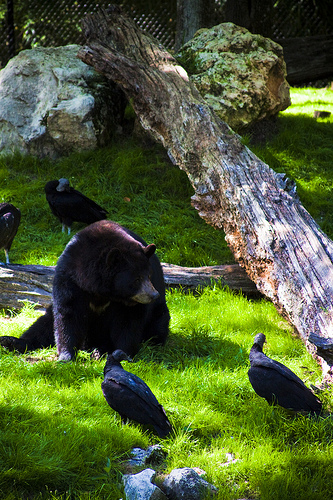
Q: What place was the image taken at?
A: It was taken at the lawn.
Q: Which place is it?
A: It is a lawn.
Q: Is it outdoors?
A: Yes, it is outdoors.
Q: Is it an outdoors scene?
A: Yes, it is outdoors.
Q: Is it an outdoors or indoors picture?
A: It is outdoors.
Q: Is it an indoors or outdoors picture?
A: It is outdoors.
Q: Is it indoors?
A: No, it is outdoors.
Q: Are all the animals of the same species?
A: No, there are both birds and bears.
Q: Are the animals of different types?
A: Yes, they are birds and bears.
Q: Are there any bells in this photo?
A: No, there are no bells.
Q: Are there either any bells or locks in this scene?
A: No, there are no bells or locks.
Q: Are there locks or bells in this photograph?
A: No, there are no bells or locks.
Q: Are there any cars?
A: No, there are no cars.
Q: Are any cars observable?
A: No, there are no cars.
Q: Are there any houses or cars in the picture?
A: No, there are no cars or houses.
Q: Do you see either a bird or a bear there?
A: Yes, there is a bird.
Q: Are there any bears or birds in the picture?
A: Yes, there is a bird.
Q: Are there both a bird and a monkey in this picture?
A: No, there is a bird but no monkeys.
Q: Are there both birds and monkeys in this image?
A: No, there is a bird but no monkeys.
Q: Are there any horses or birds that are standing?
A: Yes, the bird is standing.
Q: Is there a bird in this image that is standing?
A: Yes, there is a bird that is standing.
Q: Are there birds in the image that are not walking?
A: Yes, there is a bird that is standing.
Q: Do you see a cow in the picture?
A: No, there are no cows.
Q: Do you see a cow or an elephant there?
A: No, there are no cows or elephants.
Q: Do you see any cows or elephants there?
A: No, there are no cows or elephants.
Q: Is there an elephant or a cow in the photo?
A: No, there are no cows or elephants.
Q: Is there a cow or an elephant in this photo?
A: No, there are no cows or elephants.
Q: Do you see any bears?
A: Yes, there is a bear.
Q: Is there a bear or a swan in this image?
A: Yes, there is a bear.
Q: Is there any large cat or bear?
A: Yes, there is a large bear.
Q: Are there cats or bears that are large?
A: Yes, the bear is large.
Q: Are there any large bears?
A: Yes, there is a large bear.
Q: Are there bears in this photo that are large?
A: Yes, there is a bear that is large.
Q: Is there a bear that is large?
A: Yes, there is a bear that is large.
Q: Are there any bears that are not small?
A: Yes, there is a large bear.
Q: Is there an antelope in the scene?
A: No, there are no antelopes.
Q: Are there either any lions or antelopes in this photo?
A: No, there are no antelopes or lions.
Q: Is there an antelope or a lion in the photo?
A: No, there are no antelopes or lions.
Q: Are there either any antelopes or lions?
A: No, there are no antelopes or lions.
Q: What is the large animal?
A: The animal is a bear.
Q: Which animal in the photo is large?
A: The animal is a bear.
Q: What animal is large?
A: The animal is a bear.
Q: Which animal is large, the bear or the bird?
A: The bear is large.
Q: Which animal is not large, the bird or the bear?
A: The bird is not large.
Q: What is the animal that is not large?
A: The animal is a bird.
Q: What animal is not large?
A: The animal is a bird.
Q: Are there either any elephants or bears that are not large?
A: No, there is a bear but it is large.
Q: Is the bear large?
A: Yes, the bear is large.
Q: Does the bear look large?
A: Yes, the bear is large.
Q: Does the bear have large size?
A: Yes, the bear is large.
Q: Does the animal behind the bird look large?
A: Yes, the bear is large.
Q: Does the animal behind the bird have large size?
A: Yes, the bear is large.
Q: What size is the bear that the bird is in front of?
A: The bear is large.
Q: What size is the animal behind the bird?
A: The bear is large.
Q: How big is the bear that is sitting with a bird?
A: The bear is large.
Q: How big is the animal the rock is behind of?
A: The bear is large.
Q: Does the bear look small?
A: No, the bear is large.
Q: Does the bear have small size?
A: No, the bear is large.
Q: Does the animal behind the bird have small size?
A: No, the bear is large.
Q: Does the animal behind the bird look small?
A: No, the bear is large.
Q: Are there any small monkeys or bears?
A: No, there is a bear but it is large.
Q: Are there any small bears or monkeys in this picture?
A: No, there is a bear but it is large.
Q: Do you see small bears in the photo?
A: No, there is a bear but it is large.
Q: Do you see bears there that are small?
A: No, there is a bear but it is large.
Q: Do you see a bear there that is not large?
A: No, there is a bear but it is large.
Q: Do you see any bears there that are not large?
A: No, there is a bear but it is large.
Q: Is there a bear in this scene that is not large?
A: No, there is a bear but it is large.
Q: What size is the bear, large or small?
A: The bear is large.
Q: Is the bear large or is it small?
A: The bear is large.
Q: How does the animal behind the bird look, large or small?
A: The bear is large.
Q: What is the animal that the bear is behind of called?
A: The animal is a bird.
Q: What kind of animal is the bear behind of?
A: The bear is behind the bird.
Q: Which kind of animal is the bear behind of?
A: The bear is behind the bird.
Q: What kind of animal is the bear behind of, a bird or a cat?
A: The bear is behind a bird.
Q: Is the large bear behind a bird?
A: Yes, the bear is behind a bird.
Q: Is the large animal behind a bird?
A: Yes, the bear is behind a bird.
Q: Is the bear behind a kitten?
A: No, the bear is behind a bird.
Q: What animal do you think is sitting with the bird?
A: The bear is sitting with the bird.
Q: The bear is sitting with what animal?
A: The bear is sitting with a bird.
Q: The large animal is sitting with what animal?
A: The bear is sitting with a bird.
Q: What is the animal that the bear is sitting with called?
A: The animal is a bird.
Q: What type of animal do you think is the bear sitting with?
A: The bear is sitting with a bird.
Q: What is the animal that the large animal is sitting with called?
A: The animal is a bird.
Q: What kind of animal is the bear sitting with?
A: The bear is sitting with a bird.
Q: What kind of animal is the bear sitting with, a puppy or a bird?
A: The bear is sitting with a bird.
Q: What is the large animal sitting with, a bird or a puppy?
A: The bear is sitting with a bird.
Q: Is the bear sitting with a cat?
A: No, the bear is sitting with a bird.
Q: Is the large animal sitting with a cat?
A: No, the bear is sitting with a bird.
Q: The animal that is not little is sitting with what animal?
A: The bear is sitting with a bird.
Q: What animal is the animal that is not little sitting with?
A: The bear is sitting with a bird.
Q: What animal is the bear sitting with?
A: The bear is sitting with a bird.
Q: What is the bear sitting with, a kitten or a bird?
A: The bear is sitting with a bird.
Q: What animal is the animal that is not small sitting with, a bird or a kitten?
A: The bear is sitting with a bird.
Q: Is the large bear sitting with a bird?
A: Yes, the bear is sitting with a bird.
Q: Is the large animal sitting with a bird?
A: Yes, the bear is sitting with a bird.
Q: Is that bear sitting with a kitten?
A: No, the bear is sitting with a bird.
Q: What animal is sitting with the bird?
A: The bear is sitting with the bird.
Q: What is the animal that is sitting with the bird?
A: The animal is a bear.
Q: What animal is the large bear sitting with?
A: The bear is sitting with a bird.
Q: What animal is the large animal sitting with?
A: The bear is sitting with a bird.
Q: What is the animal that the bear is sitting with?
A: The animal is a bird.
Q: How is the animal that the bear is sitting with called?
A: The animal is a bird.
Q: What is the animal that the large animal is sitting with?
A: The animal is a bird.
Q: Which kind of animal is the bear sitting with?
A: The bear is sitting with a bird.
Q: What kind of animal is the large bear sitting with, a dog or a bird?
A: The bear is sitting with a bird.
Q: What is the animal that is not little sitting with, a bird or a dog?
A: The bear is sitting with a bird.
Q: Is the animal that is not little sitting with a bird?
A: Yes, the bear is sitting with a bird.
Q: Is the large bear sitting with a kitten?
A: No, the bear is sitting with a bird.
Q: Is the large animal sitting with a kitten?
A: No, the bear is sitting with a bird.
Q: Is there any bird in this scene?
A: Yes, there is a bird.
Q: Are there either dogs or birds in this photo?
A: Yes, there is a bird.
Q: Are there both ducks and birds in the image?
A: No, there is a bird but no ducks.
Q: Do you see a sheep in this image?
A: No, there is no sheep.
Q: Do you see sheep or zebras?
A: No, there are no sheep or zebras.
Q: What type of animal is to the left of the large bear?
A: The animal is a bird.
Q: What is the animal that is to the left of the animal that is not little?
A: The animal is a bird.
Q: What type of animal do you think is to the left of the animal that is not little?
A: The animal is a bird.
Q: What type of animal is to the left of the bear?
A: The animal is a bird.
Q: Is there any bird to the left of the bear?
A: Yes, there is a bird to the left of the bear.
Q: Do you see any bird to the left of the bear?
A: Yes, there is a bird to the left of the bear.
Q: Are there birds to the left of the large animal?
A: Yes, there is a bird to the left of the bear.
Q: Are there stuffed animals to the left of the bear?
A: No, there is a bird to the left of the bear.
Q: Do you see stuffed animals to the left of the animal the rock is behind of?
A: No, there is a bird to the left of the bear.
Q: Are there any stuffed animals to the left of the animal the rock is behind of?
A: No, there is a bird to the left of the bear.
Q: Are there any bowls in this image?
A: No, there are no bowls.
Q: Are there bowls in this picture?
A: No, there are no bowls.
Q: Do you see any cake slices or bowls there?
A: No, there are no bowls or cake slices.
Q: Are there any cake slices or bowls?
A: No, there are no bowls or cake slices.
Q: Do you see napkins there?
A: No, there are no napkins.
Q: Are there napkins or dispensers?
A: No, there are no napkins or dispensers.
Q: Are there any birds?
A: Yes, there is a bird.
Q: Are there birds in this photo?
A: Yes, there is a bird.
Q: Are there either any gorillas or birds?
A: Yes, there is a bird.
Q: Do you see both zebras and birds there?
A: No, there is a bird but no zebras.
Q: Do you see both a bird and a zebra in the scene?
A: No, there is a bird but no zebras.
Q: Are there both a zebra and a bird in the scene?
A: No, there is a bird but no zebras.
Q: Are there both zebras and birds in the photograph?
A: No, there is a bird but no zebras.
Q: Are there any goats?
A: No, there are no goats.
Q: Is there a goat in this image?
A: No, there are no goats.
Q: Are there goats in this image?
A: No, there are no goats.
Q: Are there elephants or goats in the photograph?
A: No, there are no goats or elephants.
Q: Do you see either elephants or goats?
A: No, there are no goats or elephants.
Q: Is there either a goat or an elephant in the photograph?
A: No, there are no goats or elephants.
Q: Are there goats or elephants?
A: No, there are no goats or elephants.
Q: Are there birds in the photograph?
A: Yes, there is a bird.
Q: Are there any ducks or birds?
A: Yes, there is a bird.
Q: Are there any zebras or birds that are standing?
A: Yes, the bird is standing.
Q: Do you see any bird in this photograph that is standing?
A: Yes, there is a bird that is standing.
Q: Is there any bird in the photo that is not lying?
A: Yes, there is a bird that is standing.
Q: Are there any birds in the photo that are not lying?
A: Yes, there is a bird that is standing.